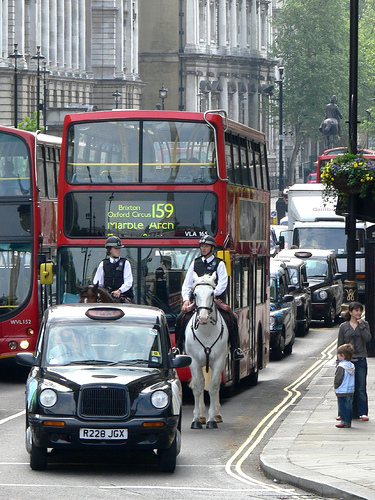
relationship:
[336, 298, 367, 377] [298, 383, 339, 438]
people on sidewalk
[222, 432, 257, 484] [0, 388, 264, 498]
lines on street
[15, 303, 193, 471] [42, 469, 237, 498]
car in street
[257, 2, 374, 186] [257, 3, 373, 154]
trees with leaves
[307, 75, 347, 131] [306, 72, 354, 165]
man statue riding a horse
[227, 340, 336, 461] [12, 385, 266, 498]
lines on road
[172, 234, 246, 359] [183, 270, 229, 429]
man riding a horse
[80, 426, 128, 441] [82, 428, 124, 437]
plate with letters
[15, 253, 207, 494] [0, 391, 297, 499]
car in street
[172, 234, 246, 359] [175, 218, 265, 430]
man on horse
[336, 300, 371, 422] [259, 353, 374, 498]
people on sidewalk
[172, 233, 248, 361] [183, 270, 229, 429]
man on horse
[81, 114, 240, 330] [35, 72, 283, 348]
window on bus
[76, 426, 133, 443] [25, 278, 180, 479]
plate on car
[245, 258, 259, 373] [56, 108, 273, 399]
doors on bus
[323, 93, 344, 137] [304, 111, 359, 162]
man statue on a horse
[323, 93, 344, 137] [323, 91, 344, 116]
man statue of horseback rider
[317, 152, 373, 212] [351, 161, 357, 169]
plant with flower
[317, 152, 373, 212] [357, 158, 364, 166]
plant with flower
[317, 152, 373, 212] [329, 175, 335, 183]
plant with flower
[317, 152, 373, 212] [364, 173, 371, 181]
plant with flower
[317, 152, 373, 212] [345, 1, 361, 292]
plant hanging from pole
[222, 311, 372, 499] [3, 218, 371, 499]
line is on road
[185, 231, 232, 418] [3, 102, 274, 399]
horse back of buses